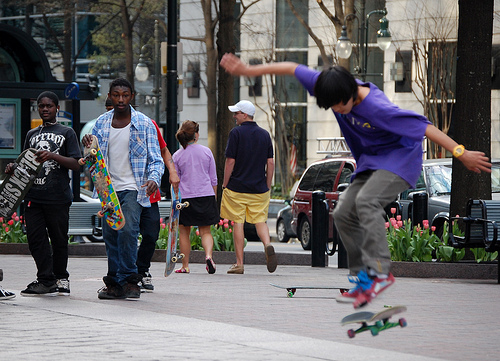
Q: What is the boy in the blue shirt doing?
A: Skateboarding.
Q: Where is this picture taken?
A: A sidewalk.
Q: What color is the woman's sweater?
A: Purple.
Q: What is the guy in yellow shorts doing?
A: Walking.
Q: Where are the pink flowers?
A: Between the road and the sidewalk.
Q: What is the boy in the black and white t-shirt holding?
A: A skateboard.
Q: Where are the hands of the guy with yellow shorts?
A: In his pockets.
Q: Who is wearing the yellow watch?
A: The boy in the blue shirt.